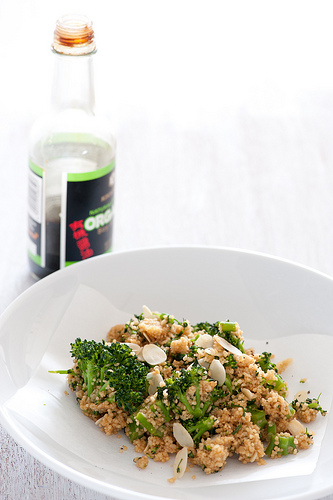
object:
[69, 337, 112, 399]
broccoli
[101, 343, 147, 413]
broccoli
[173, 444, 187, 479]
almonds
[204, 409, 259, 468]
quinoa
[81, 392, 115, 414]
quinoa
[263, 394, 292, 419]
quinoa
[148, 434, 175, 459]
quinoa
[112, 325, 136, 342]
quinoa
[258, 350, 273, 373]
brocolli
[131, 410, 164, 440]
brocolli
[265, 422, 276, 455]
brocolli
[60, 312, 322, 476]
food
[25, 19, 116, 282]
bottle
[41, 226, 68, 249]
condiment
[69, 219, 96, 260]
symbols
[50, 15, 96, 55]
top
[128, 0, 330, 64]
top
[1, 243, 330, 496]
counter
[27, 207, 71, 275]
liquid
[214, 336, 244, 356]
almonds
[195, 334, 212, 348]
almonds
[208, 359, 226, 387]
almonds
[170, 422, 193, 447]
almonds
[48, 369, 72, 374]
broccoli stem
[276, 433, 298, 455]
celery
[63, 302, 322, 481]
meal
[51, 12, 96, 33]
dispensing region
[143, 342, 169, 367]
almonds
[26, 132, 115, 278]
label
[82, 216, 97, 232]
letters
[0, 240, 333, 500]
table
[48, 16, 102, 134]
neck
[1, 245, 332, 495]
bowl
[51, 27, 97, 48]
sauce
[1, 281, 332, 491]
napkin